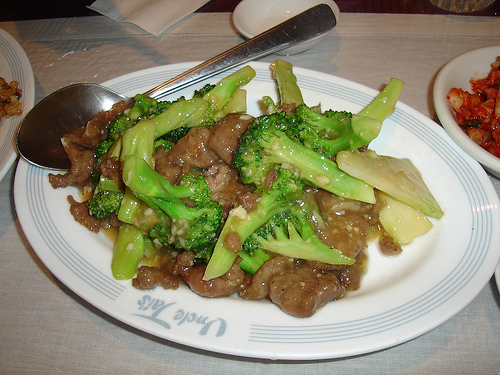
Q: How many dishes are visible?
A: 4.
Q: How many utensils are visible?
A: One.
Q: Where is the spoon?
A: On the plate.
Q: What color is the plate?
A: White and gray.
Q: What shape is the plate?
A: Circle.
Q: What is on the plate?
A: Broccoli and beef.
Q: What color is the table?
A: Gray.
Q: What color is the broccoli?
A: Green.